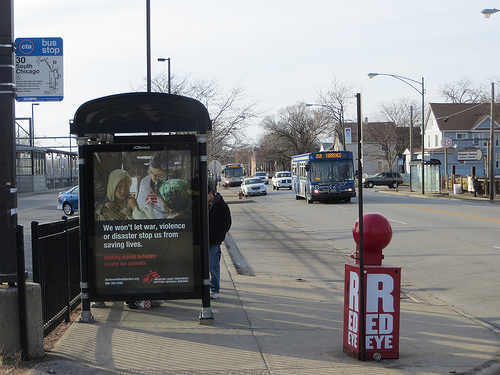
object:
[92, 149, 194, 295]
poster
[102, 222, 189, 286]
writing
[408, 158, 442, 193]
bus stop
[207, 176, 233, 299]
person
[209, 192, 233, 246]
jacket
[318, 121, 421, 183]
house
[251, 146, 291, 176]
house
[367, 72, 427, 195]
light pole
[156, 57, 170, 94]
light pole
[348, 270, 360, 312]
white letter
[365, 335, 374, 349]
white letter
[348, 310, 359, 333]
white letter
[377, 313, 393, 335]
white d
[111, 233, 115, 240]
white d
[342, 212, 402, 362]
post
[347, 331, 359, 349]
writing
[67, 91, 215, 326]
bus stop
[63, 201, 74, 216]
tire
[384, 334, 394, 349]
letter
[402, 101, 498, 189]
building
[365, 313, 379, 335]
letter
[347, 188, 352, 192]
headlights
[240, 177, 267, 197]
car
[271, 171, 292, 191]
car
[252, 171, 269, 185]
car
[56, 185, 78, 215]
blue car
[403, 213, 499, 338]
street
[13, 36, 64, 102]
sign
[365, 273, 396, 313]
letter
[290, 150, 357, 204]
bus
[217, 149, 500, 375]
road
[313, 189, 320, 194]
headlight